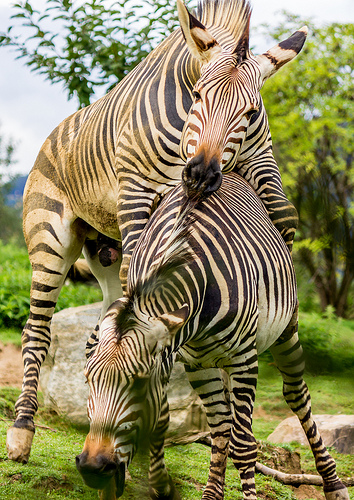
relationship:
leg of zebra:
[223, 335, 269, 480] [62, 171, 338, 494]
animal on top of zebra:
[6, 0, 309, 499] [83, 252, 324, 486]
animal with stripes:
[31, 30, 320, 324] [45, 61, 200, 207]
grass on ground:
[7, 378, 287, 487] [11, 220, 309, 487]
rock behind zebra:
[41, 299, 183, 436] [10, 36, 289, 334]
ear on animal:
[257, 23, 340, 106] [6, 0, 309, 499]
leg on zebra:
[225, 335, 259, 499] [73, 158, 314, 443]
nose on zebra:
[74, 445, 117, 474] [24, 191, 328, 481]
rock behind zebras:
[41, 299, 212, 442] [15, 30, 295, 443]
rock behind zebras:
[250, 359, 342, 479] [18, 110, 297, 463]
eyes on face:
[186, 61, 293, 146] [147, 22, 295, 263]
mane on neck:
[90, 279, 199, 344] [135, 238, 258, 409]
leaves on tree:
[304, 312, 327, 355] [233, 23, 330, 368]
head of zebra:
[53, 339, 177, 487] [24, 191, 328, 481]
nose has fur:
[108, 408, 206, 498] [139, 298, 188, 391]